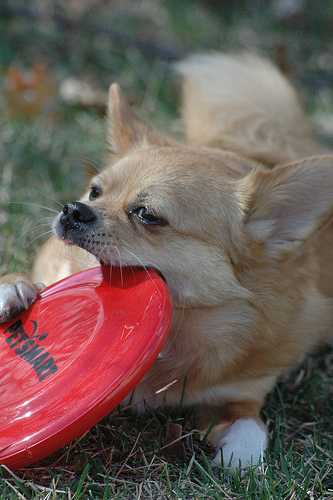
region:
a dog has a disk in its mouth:
[6, 234, 208, 472]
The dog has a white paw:
[173, 406, 316, 497]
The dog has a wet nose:
[55, 191, 111, 250]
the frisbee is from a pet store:
[4, 233, 198, 493]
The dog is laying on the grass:
[11, 125, 331, 498]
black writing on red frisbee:
[0, 314, 60, 386]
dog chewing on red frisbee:
[0, 47, 331, 499]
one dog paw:
[0, 265, 47, 329]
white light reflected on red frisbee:
[8, 387, 52, 428]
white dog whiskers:
[3, 181, 64, 252]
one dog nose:
[55, 196, 100, 229]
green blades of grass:
[272, 432, 310, 489]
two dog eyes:
[83, 173, 173, 234]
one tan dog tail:
[163, 41, 323, 166]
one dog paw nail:
[13, 284, 34, 312]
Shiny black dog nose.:
[59, 201, 95, 231]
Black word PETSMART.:
[2, 319, 58, 381]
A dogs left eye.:
[133, 206, 161, 223]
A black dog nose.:
[55, 201, 92, 230]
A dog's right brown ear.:
[107, 83, 173, 153]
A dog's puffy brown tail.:
[175, 54, 325, 153]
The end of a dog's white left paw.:
[212, 419, 267, 474]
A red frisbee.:
[0, 263, 171, 476]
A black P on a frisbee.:
[0, 317, 22, 334]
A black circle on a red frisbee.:
[38, 331, 48, 341]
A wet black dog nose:
[59, 196, 93, 228]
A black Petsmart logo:
[3, 318, 60, 388]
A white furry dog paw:
[210, 421, 269, 476]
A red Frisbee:
[10, 267, 198, 466]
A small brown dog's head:
[60, 78, 318, 297]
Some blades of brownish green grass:
[292, 427, 330, 477]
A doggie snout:
[56, 199, 127, 267]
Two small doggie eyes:
[91, 181, 169, 233]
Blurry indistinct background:
[24, 7, 131, 61]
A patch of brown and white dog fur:
[206, 310, 266, 381]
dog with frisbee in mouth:
[0, 82, 328, 482]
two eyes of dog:
[87, 184, 163, 222]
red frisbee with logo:
[0, 261, 172, 471]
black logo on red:
[3, 319, 58, 383]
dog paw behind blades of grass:
[177, 409, 294, 498]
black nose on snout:
[55, 199, 111, 243]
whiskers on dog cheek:
[88, 234, 161, 295]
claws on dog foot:
[0, 271, 43, 321]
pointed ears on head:
[106, 83, 330, 248]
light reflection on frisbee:
[0, 264, 108, 450]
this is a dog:
[25, 65, 297, 418]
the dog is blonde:
[91, 144, 247, 321]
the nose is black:
[43, 196, 104, 246]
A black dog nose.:
[62, 199, 95, 228]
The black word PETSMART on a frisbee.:
[2, 318, 59, 380]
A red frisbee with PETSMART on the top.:
[0, 263, 172, 470]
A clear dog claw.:
[14, 283, 29, 310]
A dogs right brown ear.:
[108, 81, 164, 157]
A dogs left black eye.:
[141, 209, 157, 221]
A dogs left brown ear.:
[248, 154, 331, 244]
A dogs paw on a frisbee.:
[0, 273, 46, 321]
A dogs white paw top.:
[211, 416, 270, 475]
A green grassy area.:
[2, 351, 331, 498]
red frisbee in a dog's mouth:
[1, 258, 173, 471]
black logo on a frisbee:
[1, 315, 60, 382]